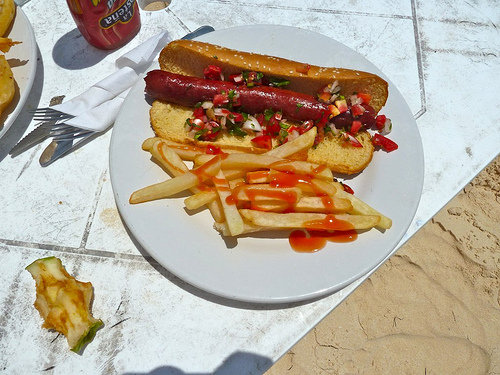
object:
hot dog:
[142, 68, 378, 134]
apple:
[24, 256, 104, 354]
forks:
[28, 25, 216, 125]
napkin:
[46, 28, 172, 119]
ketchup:
[188, 152, 232, 193]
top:
[2, 4, 495, 372]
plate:
[107, 22, 427, 311]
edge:
[153, 254, 340, 306]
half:
[67, 0, 143, 53]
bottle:
[64, 0, 143, 53]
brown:
[47, 295, 63, 313]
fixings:
[182, 61, 398, 154]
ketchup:
[63, 0, 142, 51]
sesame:
[247, 63, 252, 68]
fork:
[41, 87, 132, 142]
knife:
[5, 113, 86, 157]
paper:
[62, 85, 133, 134]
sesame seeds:
[224, 57, 229, 63]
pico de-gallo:
[250, 135, 272, 152]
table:
[0, 0, 498, 372]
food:
[126, 125, 393, 255]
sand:
[264, 155, 500, 374]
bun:
[142, 37, 392, 177]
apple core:
[24, 256, 107, 355]